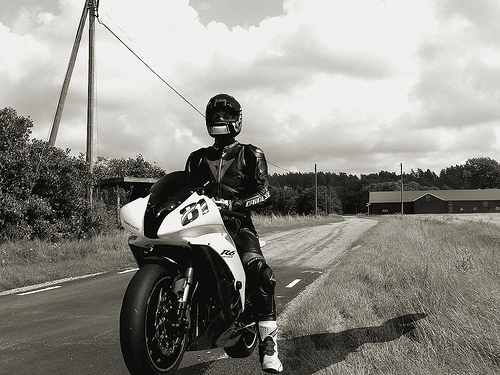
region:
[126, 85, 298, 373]
person sitting on motorbike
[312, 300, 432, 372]
shadow on top of grass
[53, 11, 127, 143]
two poles and wire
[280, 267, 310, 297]
white line in road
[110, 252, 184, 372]
front tire of bike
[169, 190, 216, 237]
number on front of bike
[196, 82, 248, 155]
helmet on rider's head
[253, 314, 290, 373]
white boot on rider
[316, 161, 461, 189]
tree tops on horizon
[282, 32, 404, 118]
white clouds in daytime sky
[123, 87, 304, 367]
man on motorcycle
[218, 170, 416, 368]
shadow of man on grass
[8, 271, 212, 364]
paved road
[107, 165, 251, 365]
white and black motorcycle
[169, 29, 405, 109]
cloudy day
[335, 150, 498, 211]
long brown building during cloudy day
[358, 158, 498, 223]
trees behind long building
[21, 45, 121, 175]
two telephone poles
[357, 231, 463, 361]
dry grass on sunny day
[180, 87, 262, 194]
man with black helmet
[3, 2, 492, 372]
black and white filter.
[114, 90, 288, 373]
man on a motorcycle.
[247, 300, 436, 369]
shadow on the grass.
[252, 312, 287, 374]
person's boot is white.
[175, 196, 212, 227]
bike is number 81.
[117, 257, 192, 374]
the wheel is black.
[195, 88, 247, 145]
person wearing a black helmet.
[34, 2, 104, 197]
wooden poles in distance.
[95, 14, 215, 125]
the wire is black.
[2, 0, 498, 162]
the sky is cloudy.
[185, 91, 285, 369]
a man on a motorcycle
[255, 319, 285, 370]
a black and white boot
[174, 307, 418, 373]
the shadow of a man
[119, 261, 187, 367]
a black bike wheel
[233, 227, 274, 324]
the leg of a man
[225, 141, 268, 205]
the arm of a man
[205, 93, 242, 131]
a black and white helmet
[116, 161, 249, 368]
a black and white bike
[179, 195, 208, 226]
the number 81 on a bike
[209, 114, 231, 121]
sunglasses of a man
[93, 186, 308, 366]
the motorbike is white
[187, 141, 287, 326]
the gear is reflective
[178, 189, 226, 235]
number 81 is on the front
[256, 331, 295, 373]
the shoes are white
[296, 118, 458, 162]
the clouds are in the sky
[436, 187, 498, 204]
the roof is grey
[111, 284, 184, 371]
the tire is made of rubber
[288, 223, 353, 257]
the road is untarmaced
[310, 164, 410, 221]
the poles are wooden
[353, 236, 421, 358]
the grass is brown and dry